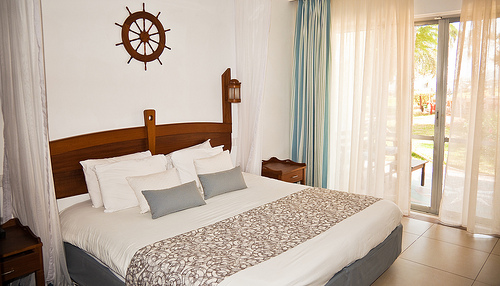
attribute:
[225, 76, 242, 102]
lantern — wooden, small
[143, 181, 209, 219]
cushion — gray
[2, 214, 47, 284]
table — wooden, here, wood, small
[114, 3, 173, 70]
wheel — wooden, large, brow, for ship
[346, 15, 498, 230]
door — metal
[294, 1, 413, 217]
curtains — blue, white, shimmer, sheer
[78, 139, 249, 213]
pillows — white, gre, small, blue, propped, gra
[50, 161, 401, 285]
cover — white, blue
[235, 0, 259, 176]
net — white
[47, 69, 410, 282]
bed — dark, large, made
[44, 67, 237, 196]
headboard — wood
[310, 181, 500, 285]
floor — tile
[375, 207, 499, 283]
tiles — white, floored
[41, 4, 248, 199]
wall — white